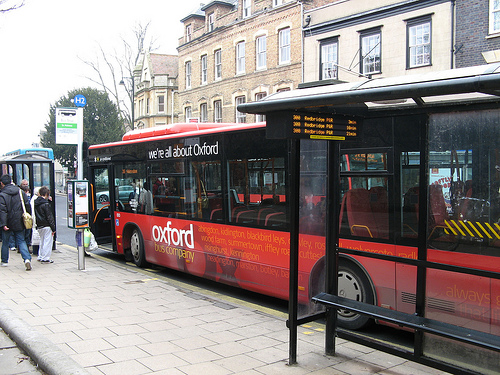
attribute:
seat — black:
[310, 287, 499, 353]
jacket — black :
[33, 199, 50, 226]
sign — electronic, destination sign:
[292, 113, 357, 138]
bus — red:
[83, 111, 497, 346]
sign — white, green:
[10, 113, 110, 168]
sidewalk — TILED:
[2, 230, 459, 372]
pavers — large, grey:
[2, 242, 452, 373]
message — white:
[140, 144, 228, 166]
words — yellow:
[289, 113, 361, 138]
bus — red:
[84, 118, 499, 373]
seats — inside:
[205, 204, 283, 226]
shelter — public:
[226, 55, 499, 372]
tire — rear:
[310, 258, 378, 333]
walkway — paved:
[28, 270, 222, 373]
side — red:
[85, 120, 498, 374]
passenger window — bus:
[217, 161, 290, 233]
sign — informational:
[63, 108, 93, 147]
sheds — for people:
[274, 73, 498, 353]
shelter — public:
[0, 151, 65, 257]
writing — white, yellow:
[152, 221, 194, 262]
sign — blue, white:
[66, 181, 91, 233]